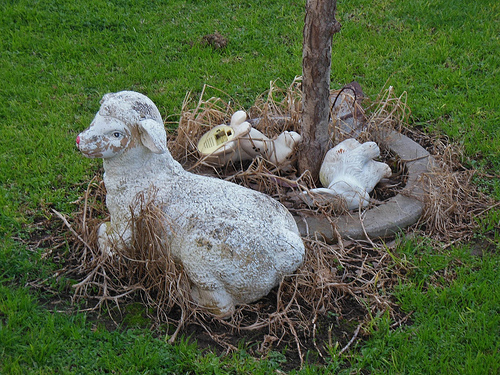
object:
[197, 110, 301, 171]
bunny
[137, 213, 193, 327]
weeds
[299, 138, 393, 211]
bunny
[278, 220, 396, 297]
sticks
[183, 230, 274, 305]
thigh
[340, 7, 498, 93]
grass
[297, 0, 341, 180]
tree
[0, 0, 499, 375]
ground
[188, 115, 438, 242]
stones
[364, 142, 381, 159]
paw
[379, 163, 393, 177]
paw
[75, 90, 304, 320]
clock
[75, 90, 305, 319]
sheep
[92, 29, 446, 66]
green grass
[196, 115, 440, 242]
barrier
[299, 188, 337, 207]
ear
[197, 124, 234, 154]
bottom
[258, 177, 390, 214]
sticks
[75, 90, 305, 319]
figure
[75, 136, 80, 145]
nose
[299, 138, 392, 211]
side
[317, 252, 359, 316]
weeds